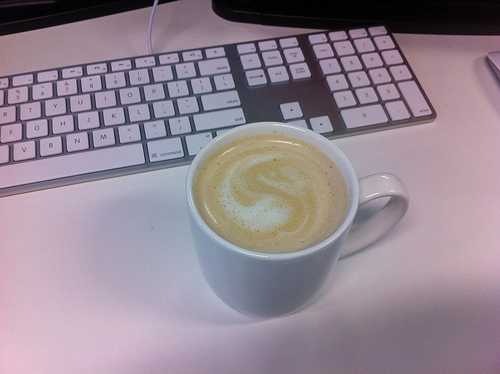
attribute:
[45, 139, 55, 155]
letter — white, b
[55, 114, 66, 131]
letter — white, h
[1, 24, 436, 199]
keyboard — white, Apple, USB, SILVER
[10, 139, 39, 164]
v key — white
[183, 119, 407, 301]
cup — WHITE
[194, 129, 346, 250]
liquid — WHITE, LIGHT BROWN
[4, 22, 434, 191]
keys — WHITE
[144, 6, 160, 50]
wire — WHITE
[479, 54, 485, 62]
mouse — MAGIC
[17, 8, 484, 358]
desk — WHITE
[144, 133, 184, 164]
command key — white